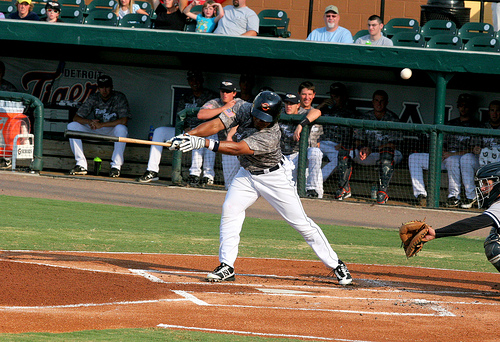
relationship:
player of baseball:
[162, 83, 363, 293] [54, 81, 360, 297]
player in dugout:
[61, 73, 132, 184] [8, 53, 487, 202]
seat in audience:
[427, 29, 464, 49] [4, 1, 497, 48]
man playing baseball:
[162, 83, 363, 293] [396, 61, 416, 81]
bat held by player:
[61, 126, 173, 150] [162, 83, 363, 293]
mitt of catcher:
[398, 211, 429, 258] [424, 159, 500, 279]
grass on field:
[4, 199, 210, 256] [3, 175, 499, 328]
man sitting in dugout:
[336, 90, 408, 201] [8, 53, 487, 202]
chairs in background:
[390, 12, 500, 56] [5, 1, 494, 28]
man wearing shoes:
[336, 90, 408, 201] [331, 182, 393, 208]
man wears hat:
[298, 1, 356, 46] [323, 3, 341, 14]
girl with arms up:
[182, 1, 227, 30] [182, 2, 226, 20]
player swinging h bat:
[162, 83, 363, 293] [61, 126, 173, 150]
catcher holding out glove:
[424, 159, 500, 279] [398, 211, 429, 258]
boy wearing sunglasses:
[353, 14, 402, 50] [366, 21, 380, 27]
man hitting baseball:
[162, 83, 363, 293] [54, 81, 360, 297]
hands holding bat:
[166, 130, 209, 158] [61, 126, 173, 150]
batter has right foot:
[162, 83, 363, 293] [202, 191, 262, 284]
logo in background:
[5, 59, 90, 108] [3, 48, 496, 105]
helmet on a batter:
[249, 88, 284, 130] [162, 83, 363, 293]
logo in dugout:
[5, 59, 90, 108] [8, 53, 487, 202]